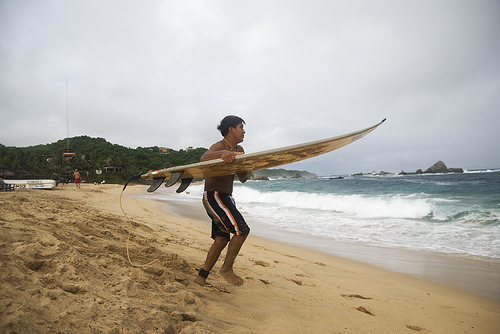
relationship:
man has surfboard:
[200, 113, 251, 290] [140, 117, 389, 196]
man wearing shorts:
[200, 113, 251, 290] [201, 189, 253, 236]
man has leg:
[200, 113, 251, 290] [221, 198, 248, 288]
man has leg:
[200, 113, 251, 290] [195, 213, 230, 289]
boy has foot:
[200, 113, 251, 290] [221, 198, 248, 288]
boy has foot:
[200, 113, 251, 290] [195, 213, 230, 289]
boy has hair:
[200, 113, 251, 290] [215, 114, 246, 136]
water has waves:
[185, 168, 497, 262] [252, 183, 477, 227]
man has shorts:
[200, 113, 251, 290] [201, 189, 253, 236]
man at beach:
[200, 113, 251, 290] [9, 171, 499, 333]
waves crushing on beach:
[252, 183, 477, 227] [9, 171, 499, 333]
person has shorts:
[72, 164, 84, 186] [75, 178, 81, 185]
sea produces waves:
[185, 168, 497, 262] [252, 183, 477, 227]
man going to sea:
[200, 113, 251, 290] [185, 168, 497, 262]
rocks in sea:
[347, 155, 469, 178] [185, 168, 497, 262]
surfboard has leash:
[140, 117, 389, 196] [114, 166, 210, 278]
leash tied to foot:
[114, 166, 210, 278] [206, 214, 228, 282]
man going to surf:
[200, 113, 251, 290] [185, 168, 497, 262]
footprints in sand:
[247, 244, 417, 333] [4, 180, 499, 331]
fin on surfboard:
[145, 173, 164, 194] [140, 117, 389, 196]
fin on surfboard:
[166, 169, 184, 189] [140, 117, 389, 196]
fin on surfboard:
[177, 176, 197, 195] [140, 117, 389, 196]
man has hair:
[200, 113, 251, 290] [215, 114, 246, 136]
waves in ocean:
[252, 183, 477, 227] [185, 168, 497, 262]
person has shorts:
[72, 164, 84, 186] [74, 176, 83, 183]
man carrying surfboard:
[200, 113, 251, 290] [140, 117, 389, 196]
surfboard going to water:
[140, 117, 389, 196] [185, 168, 497, 262]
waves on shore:
[252, 183, 477, 227] [157, 177, 500, 303]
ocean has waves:
[185, 168, 497, 262] [252, 183, 477, 227]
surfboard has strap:
[140, 117, 389, 196] [114, 166, 210, 278]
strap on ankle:
[114, 166, 210, 278] [195, 213, 230, 289]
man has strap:
[200, 113, 251, 290] [114, 166, 210, 278]